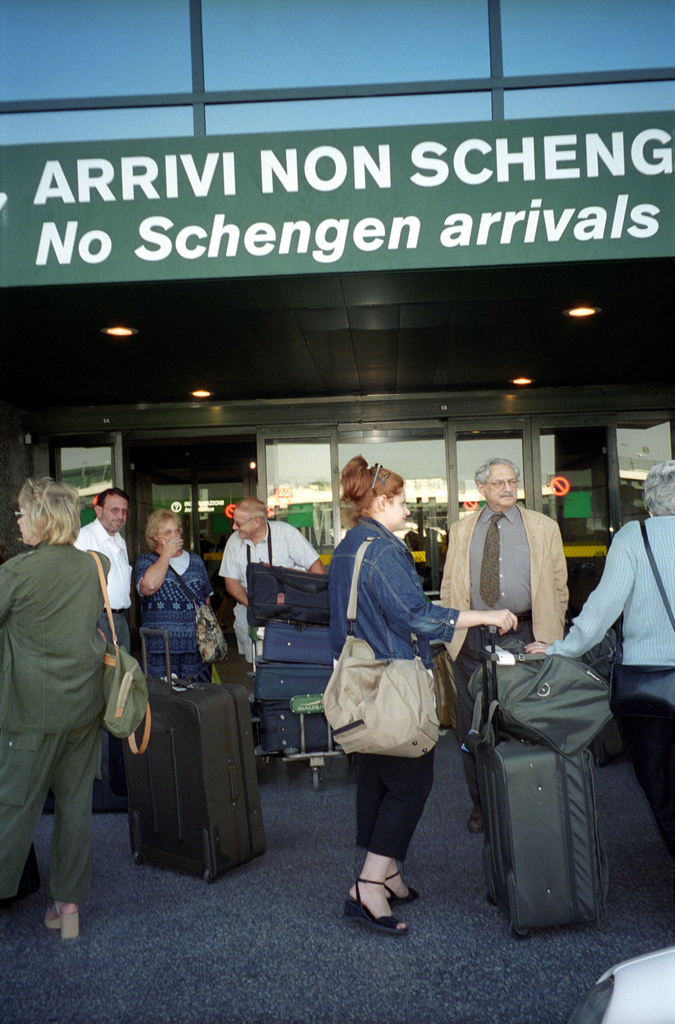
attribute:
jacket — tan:
[442, 506, 570, 660]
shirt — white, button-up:
[73, 516, 134, 612]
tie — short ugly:
[473, 506, 524, 606]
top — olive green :
[2, 532, 117, 727]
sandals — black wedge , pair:
[338, 866, 425, 935]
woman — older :
[528, 455, 654, 885]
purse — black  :
[601, 513, 652, 744]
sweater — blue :
[542, 514, 653, 667]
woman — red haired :
[322, 459, 499, 945]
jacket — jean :
[315, 510, 469, 686]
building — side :
[4, 7, 653, 794]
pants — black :
[336, 752, 442, 852]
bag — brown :
[326, 533, 441, 761]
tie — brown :
[481, 509, 505, 607]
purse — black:
[605, 660, 652, 725]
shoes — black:
[339, 872, 422, 943]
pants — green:
[7, 711, 105, 904]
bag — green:
[87, 547, 154, 748]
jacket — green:
[6, 536, 115, 727]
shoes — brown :
[43, 903, 85, 942]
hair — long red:
[333, 450, 387, 510]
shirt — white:
[79, 514, 139, 610]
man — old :
[74, 481, 132, 785]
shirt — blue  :
[142, 551, 209, 651]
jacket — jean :
[325, 516, 471, 686]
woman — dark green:
[1, 470, 140, 944]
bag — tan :
[317, 530, 440, 771]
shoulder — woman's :
[336, 525, 414, 607]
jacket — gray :
[550, 522, 651, 674]